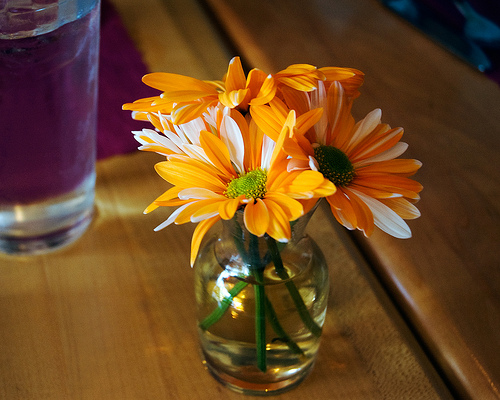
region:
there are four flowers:
[124, 59, 426, 254]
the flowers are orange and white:
[169, 136, 318, 233]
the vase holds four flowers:
[193, 243, 328, 365]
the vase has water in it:
[182, 250, 325, 380]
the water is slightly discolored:
[186, 260, 341, 377]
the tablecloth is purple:
[2, 33, 150, 162]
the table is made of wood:
[42, 113, 467, 360]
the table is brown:
[4, 75, 486, 370]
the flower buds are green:
[222, 174, 257, 196]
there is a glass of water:
[0, 19, 105, 296]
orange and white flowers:
[157, 77, 382, 227]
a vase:
[201, 250, 320, 380]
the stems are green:
[214, 260, 311, 364]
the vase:
[195, 248, 319, 388]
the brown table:
[37, 293, 137, 382]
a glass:
[3, 1, 113, 251]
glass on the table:
[10, 5, 96, 250]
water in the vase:
[198, 270, 227, 307]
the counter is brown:
[395, 58, 467, 124]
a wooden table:
[44, 290, 162, 361]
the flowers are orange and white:
[126, 58, 419, 240]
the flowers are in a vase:
[120, 58, 423, 390]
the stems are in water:
[201, 220, 316, 371]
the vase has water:
[201, 220, 325, 388]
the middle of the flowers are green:
[123, 59, 426, 240]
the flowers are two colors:
[118, 58, 420, 392]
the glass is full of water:
[0, 0, 100, 260]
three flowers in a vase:
[126, 55, 418, 390]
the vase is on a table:
[196, 202, 324, 398]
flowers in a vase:
[116, 43, 429, 398]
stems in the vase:
[197, 267, 324, 388]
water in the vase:
[265, 282, 290, 312]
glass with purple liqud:
[7, 27, 97, 262]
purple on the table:
[104, 50, 132, 159]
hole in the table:
[362, 266, 419, 311]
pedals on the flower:
[206, 80, 253, 107]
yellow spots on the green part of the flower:
[312, 155, 323, 170]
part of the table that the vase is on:
[78, 293, 134, 376]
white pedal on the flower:
[217, 123, 247, 158]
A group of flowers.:
[125, 53, 440, 278]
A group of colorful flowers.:
[107, 35, 459, 270]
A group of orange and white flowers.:
[109, 34, 434, 281]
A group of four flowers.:
[91, 38, 428, 293]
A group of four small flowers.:
[93, 27, 430, 294]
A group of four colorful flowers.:
[113, 37, 421, 293]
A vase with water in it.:
[138, 165, 358, 383]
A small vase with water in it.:
[155, 181, 355, 391]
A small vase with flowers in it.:
[128, 165, 368, 395]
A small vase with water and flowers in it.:
[120, 158, 348, 398]